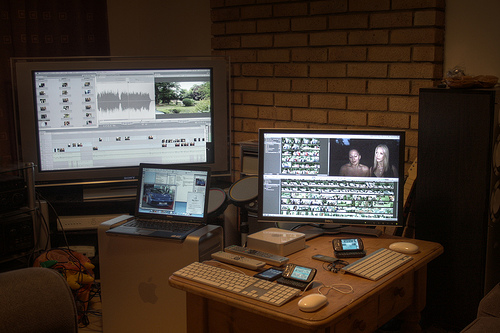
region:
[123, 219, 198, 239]
Black laptop key board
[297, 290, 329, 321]
White computer mouse in the front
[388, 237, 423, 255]
White mouse in the back of desk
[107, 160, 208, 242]
Black laptop turned on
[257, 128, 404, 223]
Large computer monitor turned on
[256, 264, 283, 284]
Cell phone laying flat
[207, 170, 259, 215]
Part of drums for video game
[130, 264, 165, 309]
Apple sympol on the side of computer equiptment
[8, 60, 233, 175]
Large television screen that is on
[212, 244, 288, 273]
Two remotes on table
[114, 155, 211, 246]
the lap top is open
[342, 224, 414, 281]
the keys are white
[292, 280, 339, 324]
the mouse is white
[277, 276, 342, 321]
the mouse is on the desk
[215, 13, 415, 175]
the wall is beige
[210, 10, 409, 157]
the wall is made of bricks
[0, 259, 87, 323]
the chair is grey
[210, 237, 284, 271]
remotes on the table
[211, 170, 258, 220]
electronic drum pads behind the monitors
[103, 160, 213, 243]
open black laptop computer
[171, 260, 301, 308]
keyboard for an Apple computer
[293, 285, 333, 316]
white Apple computer mouse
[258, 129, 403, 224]
monitor with software window displayed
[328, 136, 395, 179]
two women on the monitor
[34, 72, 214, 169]
large monitor showing a sound editing program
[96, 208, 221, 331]
Apple desktop computer tower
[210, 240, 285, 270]
two remote controls on the table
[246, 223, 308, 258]
small white apple computer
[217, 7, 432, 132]
A brick accent wall.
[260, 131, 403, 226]
Computer screen on a desk.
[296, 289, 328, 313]
White mouse on desk.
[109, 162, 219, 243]
An open black laptop.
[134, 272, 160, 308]
Apple logo on side of computer tower.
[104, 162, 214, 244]
A laptop on top of a computer tower.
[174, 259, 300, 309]
White keyboard on top of desk.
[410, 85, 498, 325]
Tall black speaker.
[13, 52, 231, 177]
Large television screen.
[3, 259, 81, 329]
The arm of a chair.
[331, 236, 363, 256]
electronic device on the table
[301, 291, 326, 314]
electronic device on the table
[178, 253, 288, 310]
electronic device on the table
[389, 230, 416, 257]
electronic device on the table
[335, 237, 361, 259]
electronic device on the table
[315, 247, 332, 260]
electronic device on the table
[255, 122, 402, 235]
electronic device on the table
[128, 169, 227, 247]
electronic device on the table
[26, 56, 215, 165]
electronic device on the table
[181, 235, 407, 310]
keyboards on the desk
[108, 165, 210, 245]
open black laptop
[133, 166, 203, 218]
screen of the laptop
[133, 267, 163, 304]
grey apple logo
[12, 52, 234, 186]
flatscreen tv with gray frame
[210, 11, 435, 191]
white brick wall with black grout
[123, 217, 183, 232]
keyboard on the black laptop